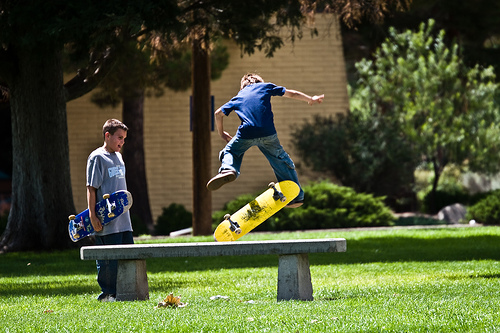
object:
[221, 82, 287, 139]
shirt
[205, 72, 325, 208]
boy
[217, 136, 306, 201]
jeans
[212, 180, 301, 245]
skateboard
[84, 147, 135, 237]
shirt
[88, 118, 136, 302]
boy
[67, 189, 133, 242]
skateboard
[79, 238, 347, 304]
bench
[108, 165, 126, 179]
letters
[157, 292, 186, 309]
leaf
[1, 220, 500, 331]
grass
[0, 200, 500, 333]
park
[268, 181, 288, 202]
wheels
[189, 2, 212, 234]
pole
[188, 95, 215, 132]
sign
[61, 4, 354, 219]
building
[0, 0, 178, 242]
tree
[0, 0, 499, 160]
background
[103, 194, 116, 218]
wheels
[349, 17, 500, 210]
tree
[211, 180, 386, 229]
bushes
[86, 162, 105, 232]
arm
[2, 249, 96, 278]
shadow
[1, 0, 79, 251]
trunk